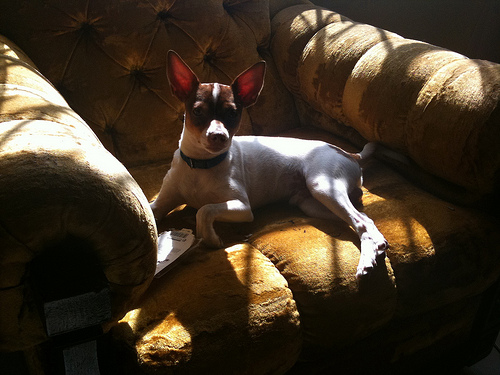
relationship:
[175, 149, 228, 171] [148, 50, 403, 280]
collar on dog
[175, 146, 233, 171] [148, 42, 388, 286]
collar on dog